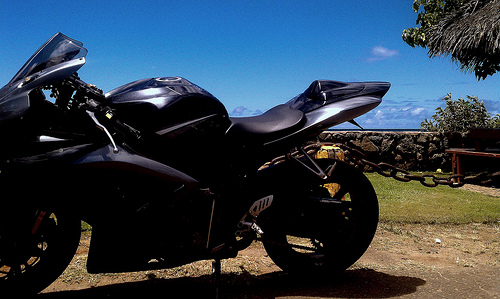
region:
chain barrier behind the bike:
[362, 148, 498, 200]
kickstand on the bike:
[210, 249, 231, 296]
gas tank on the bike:
[106, 72, 228, 134]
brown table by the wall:
[445, 140, 497, 171]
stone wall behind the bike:
[356, 132, 439, 174]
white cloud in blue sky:
[360, 40, 398, 62]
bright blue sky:
[169, 18, 326, 59]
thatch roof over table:
[436, 5, 498, 73]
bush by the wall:
[419, 89, 487, 139]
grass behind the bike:
[394, 185, 474, 222]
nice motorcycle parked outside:
[12, 29, 404, 283]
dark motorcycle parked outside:
[16, 31, 401, 278]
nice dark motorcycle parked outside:
[19, 24, 397, 287]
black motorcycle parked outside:
[5, 24, 396, 283]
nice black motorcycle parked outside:
[13, 37, 384, 289]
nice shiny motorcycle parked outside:
[8, 31, 397, 283]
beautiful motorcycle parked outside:
[7, 35, 392, 277]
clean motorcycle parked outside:
[6, 31, 398, 283]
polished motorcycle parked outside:
[11, 32, 395, 287]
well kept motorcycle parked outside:
[12, 34, 403, 285]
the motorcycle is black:
[7, 20, 373, 296]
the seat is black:
[209, 90, 316, 148]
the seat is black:
[196, 96, 391, 190]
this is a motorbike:
[9, 39, 394, 274]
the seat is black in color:
[230, 100, 314, 135]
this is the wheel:
[344, 173, 381, 240]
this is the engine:
[121, 78, 210, 125]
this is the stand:
[197, 250, 232, 274]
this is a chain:
[395, 158, 457, 198]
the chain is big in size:
[406, 161, 453, 194]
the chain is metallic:
[410, 163, 451, 193]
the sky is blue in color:
[155, 1, 223, 58]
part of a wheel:
[303, 254, 318, 269]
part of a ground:
[418, 230, 452, 277]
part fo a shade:
[372, 269, 382, 281]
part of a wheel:
[333, 200, 373, 279]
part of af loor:
[389, 223, 424, 279]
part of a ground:
[435, 225, 449, 248]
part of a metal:
[222, 160, 282, 231]